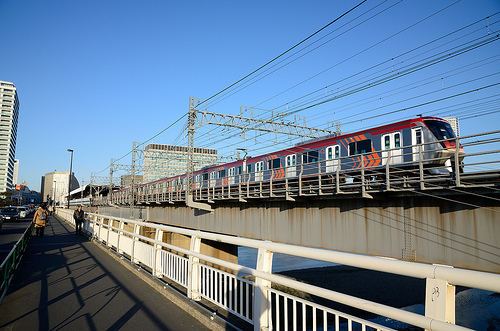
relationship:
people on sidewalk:
[32, 204, 88, 237] [17, 206, 209, 329]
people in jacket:
[32, 206, 48, 237] [34, 209, 49, 227]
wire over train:
[158, 0, 499, 119] [112, 117, 465, 202]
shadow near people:
[2, 227, 88, 284] [32, 204, 88, 237]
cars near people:
[1, 202, 38, 224] [32, 204, 88, 237]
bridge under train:
[91, 183, 498, 271] [112, 117, 465, 202]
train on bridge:
[112, 117, 465, 202] [91, 183, 498, 271]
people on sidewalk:
[32, 206, 48, 237] [17, 206, 209, 329]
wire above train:
[158, 0, 499, 119] [112, 117, 465, 202]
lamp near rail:
[68, 149, 73, 210] [49, 204, 499, 330]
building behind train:
[143, 144, 217, 185] [112, 117, 465, 202]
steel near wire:
[188, 97, 199, 209] [158, 0, 499, 119]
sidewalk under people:
[17, 206, 209, 329] [32, 204, 88, 237]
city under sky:
[1, 81, 219, 219] [1, 0, 497, 179]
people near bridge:
[32, 204, 88, 237] [91, 183, 498, 271]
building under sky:
[143, 144, 217, 185] [1, 0, 497, 179]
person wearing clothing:
[73, 205, 85, 234] [70, 207, 90, 227]